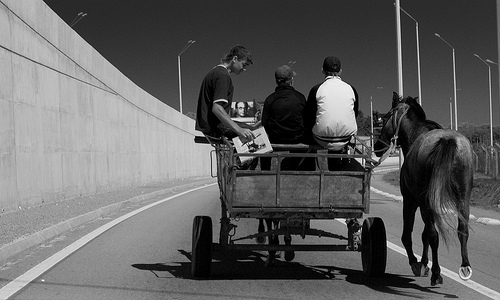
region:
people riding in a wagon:
[179, 17, 469, 298]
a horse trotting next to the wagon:
[383, 88, 494, 293]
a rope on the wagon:
[217, 152, 231, 187]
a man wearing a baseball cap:
[313, 42, 360, 144]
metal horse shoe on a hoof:
[453, 260, 478, 282]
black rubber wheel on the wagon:
[181, 214, 217, 279]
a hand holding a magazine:
[238, 123, 255, 142]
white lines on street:
[61, 227, 102, 250]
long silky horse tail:
[426, 143, 457, 220]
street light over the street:
[433, 25, 498, 123]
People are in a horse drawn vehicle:
[143, 20, 493, 285]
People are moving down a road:
[115, 15, 487, 285]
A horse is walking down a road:
[166, 32, 486, 288]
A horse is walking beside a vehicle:
[160, 21, 486, 288]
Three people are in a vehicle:
[161, 35, 387, 285]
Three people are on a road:
[173, 31, 395, 291]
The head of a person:
[220, 42, 248, 72]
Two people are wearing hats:
[258, 43, 360, 154]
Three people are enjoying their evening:
[171, 21, 496, 289]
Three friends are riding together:
[172, 20, 387, 281]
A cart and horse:
[187, 38, 484, 292]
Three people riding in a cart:
[187, 36, 390, 294]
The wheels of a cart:
[185, 209, 395, 287]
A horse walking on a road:
[373, 88, 485, 296]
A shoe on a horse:
[454, 261, 476, 286]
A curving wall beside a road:
[5, 4, 193, 284]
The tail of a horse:
[418, 134, 471, 254]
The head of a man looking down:
[219, 40, 256, 82]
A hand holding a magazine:
[229, 124, 277, 164]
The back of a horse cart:
[175, 129, 393, 291]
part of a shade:
[276, 254, 307, 285]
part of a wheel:
[196, 248, 218, 280]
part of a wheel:
[181, 216, 227, 274]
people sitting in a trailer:
[193, 43, 358, 149]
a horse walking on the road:
[372, 88, 475, 286]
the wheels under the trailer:
[191, 215, 386, 278]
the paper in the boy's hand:
[231, 125, 271, 161]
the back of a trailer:
[210, 133, 369, 218]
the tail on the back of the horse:
[425, 135, 471, 244]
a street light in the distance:
[176, 36, 197, 112]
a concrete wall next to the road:
[1, 0, 225, 212]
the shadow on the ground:
[132, 240, 457, 297]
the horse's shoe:
[459, 268, 472, 280]